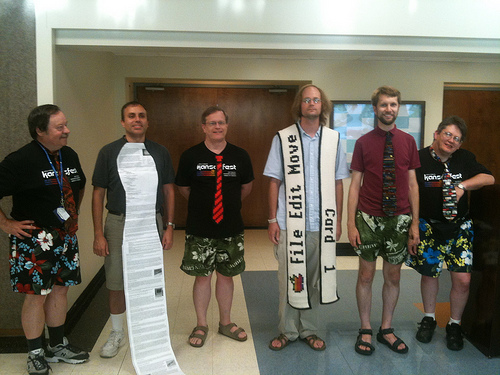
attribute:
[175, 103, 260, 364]
man — smiling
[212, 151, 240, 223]
tie — striped, red, black, long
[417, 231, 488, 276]
shorts — floral, hawaiian, colorful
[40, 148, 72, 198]
necklace — blue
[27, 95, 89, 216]
man — standing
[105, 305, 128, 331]
socks — white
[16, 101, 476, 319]
men — standing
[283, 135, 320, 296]
stole — black, white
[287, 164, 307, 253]
text — black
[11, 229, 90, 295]
shorts — floral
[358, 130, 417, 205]
shirt — red, mismatched, maroon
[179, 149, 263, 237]
t-shirt — black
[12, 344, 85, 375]
tennis shoes — grey, black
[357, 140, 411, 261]
clothing — mismatched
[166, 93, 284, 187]
door — large, brown, wooden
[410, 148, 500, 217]
shirt — black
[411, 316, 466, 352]
shoes — black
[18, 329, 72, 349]
socks — black